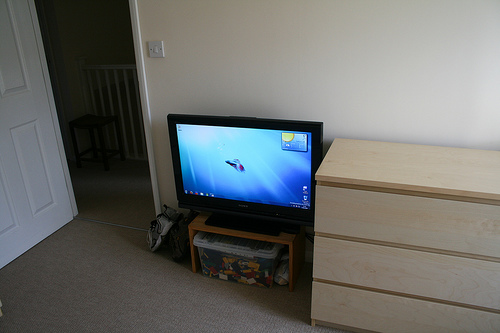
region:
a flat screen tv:
[162, 110, 318, 230]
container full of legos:
[190, 225, 295, 290]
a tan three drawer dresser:
[310, 130, 495, 322]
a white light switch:
[145, 36, 165, 57]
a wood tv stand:
[180, 211, 301, 281]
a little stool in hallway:
[66, 115, 126, 176]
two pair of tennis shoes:
[135, 196, 190, 261]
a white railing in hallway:
[76, 56, 146, 171]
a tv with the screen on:
[160, 105, 315, 236]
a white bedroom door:
[0, 2, 85, 272]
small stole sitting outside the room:
[51, 103, 133, 185]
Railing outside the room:
[63, 57, 148, 168]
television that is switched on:
[147, 102, 334, 238]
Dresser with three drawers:
[312, 126, 499, 329]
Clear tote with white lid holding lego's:
[192, 230, 284, 291]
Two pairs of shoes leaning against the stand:
[139, 204, 192, 266]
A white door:
[0, 47, 82, 266]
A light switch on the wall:
[138, 31, 165, 69]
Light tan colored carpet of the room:
[87, 261, 217, 330]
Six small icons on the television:
[181, 183, 218, 200]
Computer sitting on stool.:
[166, 111, 313, 241]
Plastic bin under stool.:
[195, 236, 277, 287]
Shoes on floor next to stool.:
[146, 204, 182, 253]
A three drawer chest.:
[309, 126, 499, 331]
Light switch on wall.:
[144, 36, 171, 64]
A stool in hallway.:
[70, 110, 125, 176]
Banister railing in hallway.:
[80, 58, 145, 166]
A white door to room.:
[4, 26, 89, 272]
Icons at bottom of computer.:
[185, 186, 222, 201]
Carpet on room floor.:
[55, 261, 150, 327]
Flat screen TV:
[145, 100, 328, 305]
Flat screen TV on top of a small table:
[146, 102, 338, 307]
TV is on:
[163, 116, 320, 310]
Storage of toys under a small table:
[166, 191, 306, 311]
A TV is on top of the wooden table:
[160, 108, 310, 297]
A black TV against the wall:
[157, 101, 328, 314]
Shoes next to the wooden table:
[143, 195, 205, 282]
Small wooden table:
[178, 213, 303, 308]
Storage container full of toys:
[193, 235, 278, 288]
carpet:
[202, 288, 284, 325]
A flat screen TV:
[168, 111, 329, 214]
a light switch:
[135, 31, 177, 64]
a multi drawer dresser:
[308, 137, 498, 325]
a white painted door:
[3, 2, 77, 276]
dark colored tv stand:
[168, 207, 310, 302]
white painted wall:
[134, 2, 499, 235]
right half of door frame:
[123, 0, 162, 214]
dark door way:
[35, 7, 157, 227]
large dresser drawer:
[316, 179, 498, 262]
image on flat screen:
[223, 146, 248, 185]